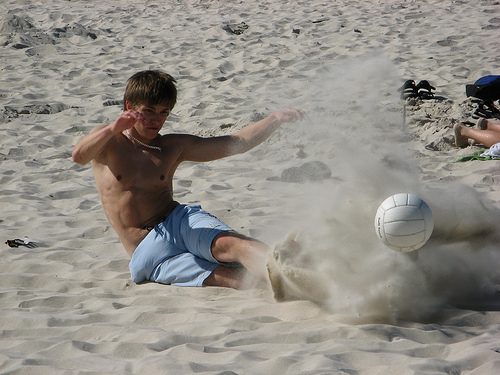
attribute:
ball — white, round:
[373, 188, 439, 261]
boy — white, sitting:
[57, 66, 326, 290]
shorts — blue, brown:
[144, 208, 227, 287]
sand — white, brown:
[3, 11, 397, 300]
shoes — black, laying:
[401, 76, 443, 107]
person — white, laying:
[461, 107, 500, 160]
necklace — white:
[132, 137, 159, 155]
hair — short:
[126, 66, 176, 104]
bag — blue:
[465, 59, 500, 110]